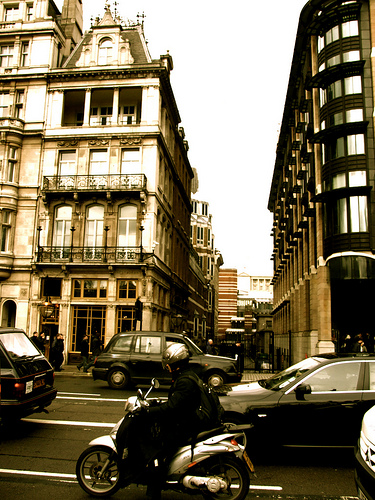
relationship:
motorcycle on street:
[72, 373, 254, 492] [7, 370, 354, 490]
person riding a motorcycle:
[127, 343, 219, 487] [72, 373, 254, 492]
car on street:
[205, 346, 359, 453] [7, 370, 354, 490]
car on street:
[5, 325, 58, 429] [7, 370, 354, 490]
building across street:
[266, 6, 362, 372] [9, 377, 351, 494]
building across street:
[32, 0, 177, 368] [7, 370, 354, 490]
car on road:
[86, 327, 245, 391] [6, 378, 361, 492]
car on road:
[213, 350, 352, 466] [6, 378, 361, 492]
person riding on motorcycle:
[140, 340, 217, 487] [72, 373, 254, 492]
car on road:
[4, 326, 55, 441] [4, 374, 349, 488]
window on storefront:
[50, 200, 77, 261] [36, 69, 155, 369]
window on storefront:
[119, 148, 144, 186] [36, 69, 155, 369]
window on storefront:
[84, 149, 111, 189] [36, 69, 155, 369]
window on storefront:
[56, 148, 76, 185] [36, 69, 155, 369]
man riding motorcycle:
[118, 337, 208, 496] [74, 378, 260, 498]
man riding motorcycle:
[117, 341, 198, 497] [74, 378, 260, 498]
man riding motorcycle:
[114, 341, 206, 499] [72, 373, 254, 492]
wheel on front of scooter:
[77, 442, 128, 498] [74, 376, 256, 498]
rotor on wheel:
[91, 462, 112, 481] [71, 442, 124, 498]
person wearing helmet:
[114, 337, 210, 498] [160, 342, 190, 362]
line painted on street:
[0, 465, 282, 498] [1, 375, 373, 499]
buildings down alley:
[215, 268, 274, 338] [160, 67, 316, 373]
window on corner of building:
[326, 192, 372, 237] [269, 0, 374, 378]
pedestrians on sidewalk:
[30, 329, 92, 372] [52, 363, 278, 383]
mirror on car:
[292, 382, 312, 394] [217, 351, 374, 454]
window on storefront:
[116, 203, 139, 257] [38, 195, 151, 363]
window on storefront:
[81, 200, 107, 262] [26, 193, 152, 366]